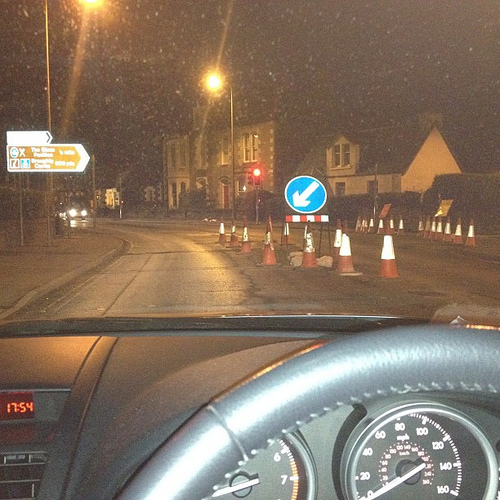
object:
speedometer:
[337, 398, 491, 498]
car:
[0, 107, 494, 495]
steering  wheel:
[303, 330, 491, 383]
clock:
[2, 398, 35, 413]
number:
[6, 403, 11, 415]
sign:
[281, 174, 330, 215]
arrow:
[291, 179, 318, 208]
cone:
[380, 232, 398, 278]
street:
[1, 216, 491, 319]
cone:
[218, 215, 226, 249]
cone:
[332, 227, 359, 279]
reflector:
[340, 236, 353, 256]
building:
[162, 97, 277, 215]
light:
[200, 436, 225, 454]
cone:
[442, 219, 451, 247]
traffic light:
[253, 166, 262, 185]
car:
[59, 203, 96, 225]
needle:
[361, 466, 423, 500]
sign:
[6, 144, 91, 175]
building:
[313, 115, 458, 203]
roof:
[297, 124, 468, 176]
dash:
[0, 333, 282, 389]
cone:
[242, 219, 253, 256]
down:
[274, 220, 284, 232]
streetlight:
[202, 65, 226, 101]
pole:
[228, 88, 238, 221]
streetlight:
[73, 0, 107, 12]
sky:
[0, 0, 500, 111]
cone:
[435, 219, 442, 244]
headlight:
[82, 210, 88, 216]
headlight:
[68, 210, 77, 218]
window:
[243, 134, 258, 164]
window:
[171, 145, 176, 168]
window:
[171, 186, 178, 206]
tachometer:
[205, 426, 311, 496]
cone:
[385, 216, 396, 233]